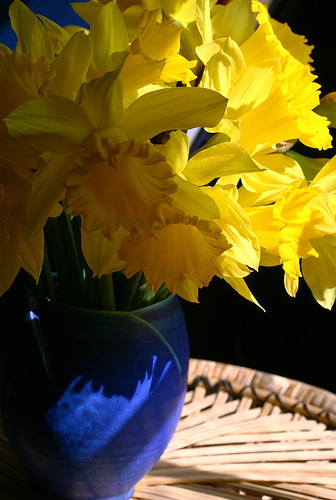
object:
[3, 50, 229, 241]
flower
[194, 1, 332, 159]
flower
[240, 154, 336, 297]
flower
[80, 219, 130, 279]
stems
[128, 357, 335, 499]
table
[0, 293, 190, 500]
vase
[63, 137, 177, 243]
yellow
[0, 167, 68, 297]
shaded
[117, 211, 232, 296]
flowers